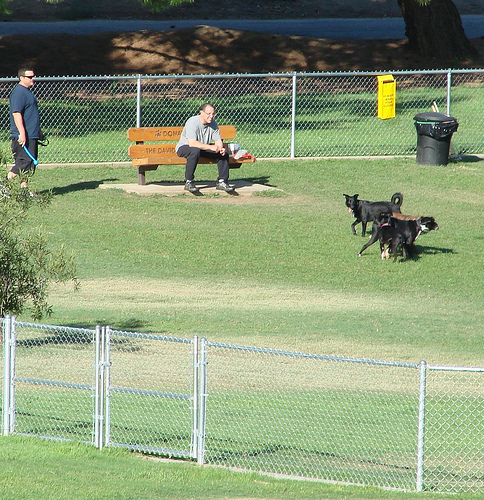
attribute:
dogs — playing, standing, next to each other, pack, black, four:
[340, 188, 432, 265]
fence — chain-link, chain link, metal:
[15, 341, 469, 489]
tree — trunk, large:
[390, 3, 466, 75]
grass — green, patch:
[28, 96, 460, 379]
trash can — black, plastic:
[416, 110, 449, 187]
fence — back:
[10, 62, 474, 150]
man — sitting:
[180, 93, 223, 180]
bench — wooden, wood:
[123, 122, 232, 169]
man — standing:
[16, 62, 46, 186]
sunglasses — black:
[23, 73, 39, 83]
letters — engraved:
[156, 128, 183, 137]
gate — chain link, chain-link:
[7, 327, 193, 467]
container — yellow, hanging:
[378, 71, 399, 123]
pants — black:
[173, 157, 217, 180]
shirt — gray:
[187, 132, 218, 155]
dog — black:
[381, 227, 428, 261]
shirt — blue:
[13, 92, 49, 135]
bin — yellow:
[370, 76, 406, 139]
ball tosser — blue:
[18, 146, 39, 165]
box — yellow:
[376, 80, 394, 114]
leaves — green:
[24, 212, 37, 232]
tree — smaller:
[0, 170, 69, 277]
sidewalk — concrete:
[1, 16, 474, 39]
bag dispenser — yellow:
[380, 77, 394, 118]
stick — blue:
[21, 148, 39, 165]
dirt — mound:
[55, 23, 380, 64]